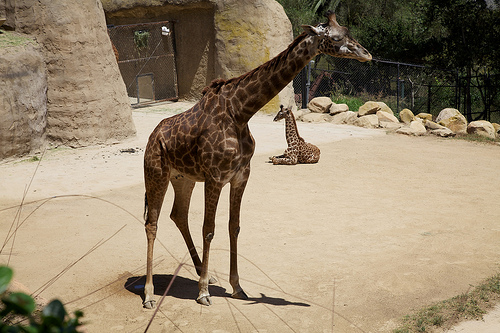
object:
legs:
[141, 177, 247, 311]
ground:
[1, 93, 496, 330]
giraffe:
[92, 6, 379, 301]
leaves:
[1, 263, 88, 329]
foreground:
[25, 205, 106, 299]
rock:
[300, 86, 500, 142]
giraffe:
[268, 98, 329, 170]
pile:
[292, 83, 472, 145]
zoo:
[2, 3, 497, 331]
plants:
[1, 267, 88, 330]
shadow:
[125, 274, 308, 307]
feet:
[143, 285, 157, 307]